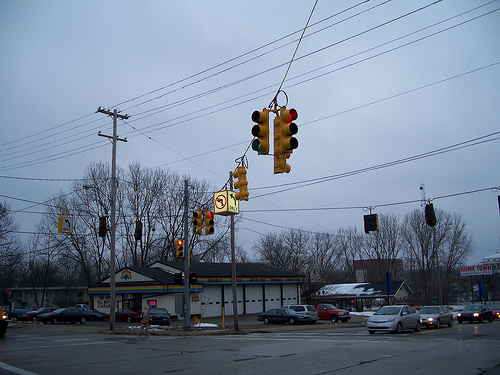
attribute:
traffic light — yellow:
[274, 104, 299, 158]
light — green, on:
[250, 138, 267, 155]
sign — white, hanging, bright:
[214, 191, 225, 214]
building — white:
[92, 260, 306, 318]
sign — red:
[147, 299, 157, 307]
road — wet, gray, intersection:
[0, 318, 499, 375]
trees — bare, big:
[29, 162, 244, 313]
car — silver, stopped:
[365, 303, 423, 335]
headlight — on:
[427, 316, 434, 324]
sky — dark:
[1, 0, 498, 281]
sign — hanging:
[227, 189, 239, 214]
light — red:
[280, 108, 297, 122]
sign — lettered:
[458, 262, 494, 279]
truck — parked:
[313, 301, 351, 324]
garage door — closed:
[199, 282, 224, 319]